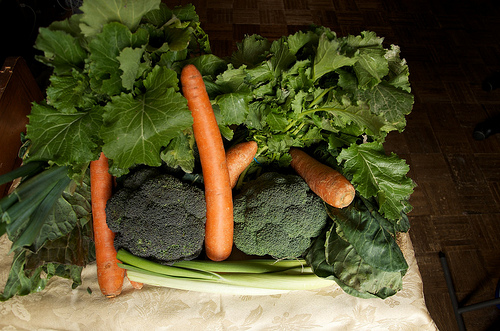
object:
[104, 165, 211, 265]
veggie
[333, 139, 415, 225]
green leaf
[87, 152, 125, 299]
orange veggie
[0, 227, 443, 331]
table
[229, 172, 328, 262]
veggie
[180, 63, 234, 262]
carrot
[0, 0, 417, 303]
pile